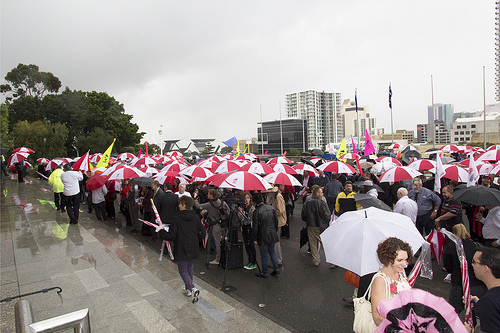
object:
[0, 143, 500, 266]
crowd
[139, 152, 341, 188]
umbrellas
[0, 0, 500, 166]
weather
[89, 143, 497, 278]
people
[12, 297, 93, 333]
stairs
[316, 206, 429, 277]
umbrella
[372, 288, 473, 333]
umbrella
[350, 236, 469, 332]
woman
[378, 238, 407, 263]
hair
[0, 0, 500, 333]
background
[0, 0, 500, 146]
sky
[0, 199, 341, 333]
ground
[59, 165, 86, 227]
man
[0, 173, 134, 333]
sidewalk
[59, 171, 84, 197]
shirt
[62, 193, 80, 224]
pants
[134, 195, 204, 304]
woman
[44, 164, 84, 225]
people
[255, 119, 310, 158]
building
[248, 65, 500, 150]
town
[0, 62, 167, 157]
trees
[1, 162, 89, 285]
road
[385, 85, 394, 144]
poles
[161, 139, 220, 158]
houses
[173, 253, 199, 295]
pants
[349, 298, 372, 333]
bag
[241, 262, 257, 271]
shoes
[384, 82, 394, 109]
flags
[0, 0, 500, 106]
clouds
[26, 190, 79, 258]
reflections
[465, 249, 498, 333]
man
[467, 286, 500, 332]
shirt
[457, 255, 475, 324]
umbrella